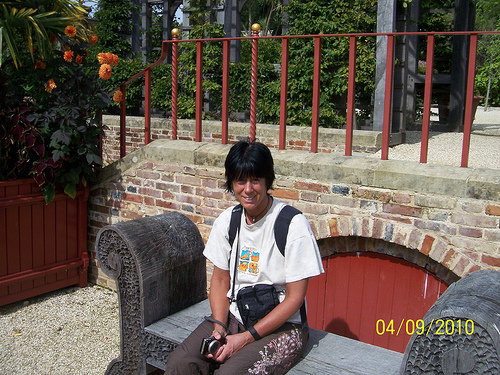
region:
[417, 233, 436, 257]
clay brick built into a wall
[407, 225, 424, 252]
clay brick built into a wall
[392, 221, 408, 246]
clay brick built into a wall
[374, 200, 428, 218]
clay brick built into a wall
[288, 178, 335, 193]
clay brick built into a wall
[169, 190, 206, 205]
clay brick built into a wall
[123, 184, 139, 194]
clay brick built into a wall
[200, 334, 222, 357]
part of a camera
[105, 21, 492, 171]
a long red rail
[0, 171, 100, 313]
part of a red planter box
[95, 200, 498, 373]
a gray outdoor bench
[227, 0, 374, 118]
a large green tree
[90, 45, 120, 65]
an orange flower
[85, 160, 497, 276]
part of a brick wall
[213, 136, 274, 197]
a man's short cut hair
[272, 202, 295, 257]
a black strap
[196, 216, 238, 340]
the arm of a man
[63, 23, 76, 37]
flower is next to flower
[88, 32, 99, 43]
flower is next to flower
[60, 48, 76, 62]
flower is next to flower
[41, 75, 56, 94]
flower is next to flower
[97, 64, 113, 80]
flower is next to flower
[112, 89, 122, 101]
flower is next to flower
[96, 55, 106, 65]
flower is next to flower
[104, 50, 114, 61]
flower is next to flower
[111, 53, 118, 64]
flower is next to flower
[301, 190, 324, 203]
brick is next to brick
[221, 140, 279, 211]
A person with short dark hair.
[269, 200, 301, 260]
A shoulder strap of a back pack.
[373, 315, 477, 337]
A time stamp on a video.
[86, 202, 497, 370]
A large cement bench.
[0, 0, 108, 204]
A large flower filled plant.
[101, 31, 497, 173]
A pink metal fence.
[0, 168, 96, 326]
A wooden planter.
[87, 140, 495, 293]
A brick wall behind a bench.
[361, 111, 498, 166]
A paved walkway.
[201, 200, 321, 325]
A woman wearing a white t shirt.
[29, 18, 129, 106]
A bunch of orange flowers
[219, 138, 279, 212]
Black hair on woman's head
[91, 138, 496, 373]
Woman sitting on a bench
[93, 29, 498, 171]
The metal railings are red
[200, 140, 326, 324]
Woman wearing a white shirt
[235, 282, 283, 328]
A black fanny pack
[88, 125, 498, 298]
Bricks on the walls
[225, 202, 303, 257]
Two black straps of a backpack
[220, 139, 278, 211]
The woman is smiling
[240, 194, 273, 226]
Necklace around lady's neck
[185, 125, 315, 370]
This is a person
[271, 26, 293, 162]
This is a metal bar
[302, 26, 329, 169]
This is a metal bar